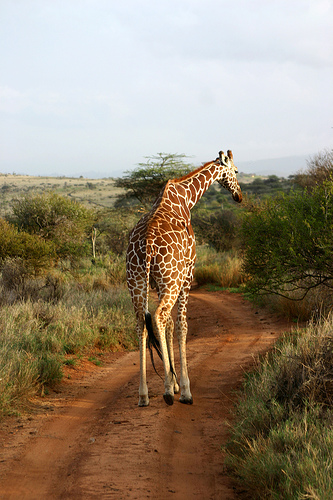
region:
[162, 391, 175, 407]
hoof barely touching the ground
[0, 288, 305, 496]
dirt road used by vehicles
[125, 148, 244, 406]
giraffe walking down a road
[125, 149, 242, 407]
giraffe with its head down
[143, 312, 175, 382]
hair of a giraffe's tail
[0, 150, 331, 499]
giraffe in the wild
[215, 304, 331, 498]
dry grass beside the road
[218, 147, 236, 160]
knobs on a giraffe's head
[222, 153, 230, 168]
right ear of a giraffe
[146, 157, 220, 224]
the mane of a giraffe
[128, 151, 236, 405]
giraffe walking down a dirt road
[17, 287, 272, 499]
a red clay dirt road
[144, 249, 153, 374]
the giraffe's tail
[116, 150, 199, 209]
tallest tree in the distance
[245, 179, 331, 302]
tree on the right next to the giraffe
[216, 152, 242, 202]
the giraffe's head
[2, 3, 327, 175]
clear skies overhead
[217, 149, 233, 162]
the giraffe's horns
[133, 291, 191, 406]
the tall giraffe's four legs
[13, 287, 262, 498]
tire tracks in the dirt road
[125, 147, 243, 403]
a giraffe on a dirt road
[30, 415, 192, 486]
a brown dirt road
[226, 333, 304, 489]
a grassy edge of a road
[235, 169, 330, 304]
a bushy tree by the road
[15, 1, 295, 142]
a blue and white sky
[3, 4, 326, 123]
a blue and white cloudy sky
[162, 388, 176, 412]
a hoof of a animal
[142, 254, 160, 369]
the tail of the aniaml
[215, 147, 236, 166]
the ear of a animal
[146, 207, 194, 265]
tan and cream coat of a animal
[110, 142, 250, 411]
giraffe walking on dirt road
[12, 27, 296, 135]
blue cloudy sky in the distance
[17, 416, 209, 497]
dirt ground where giraffe is walking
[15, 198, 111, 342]
grass and bushes near giraffe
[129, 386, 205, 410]
hooves of a giraffe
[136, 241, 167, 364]
tail of a giraffe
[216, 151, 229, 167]
right ear of a giraffe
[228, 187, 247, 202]
nose and mouth of a giraffe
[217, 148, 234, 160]
horns on a giraffe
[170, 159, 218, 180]
mane of a giraffe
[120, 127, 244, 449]
giraffe is walking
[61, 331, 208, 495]
the road is brown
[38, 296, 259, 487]
the road is made of dirt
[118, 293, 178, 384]
the tip of the tail is black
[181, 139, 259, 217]
the giraffe is looking to the right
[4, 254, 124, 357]
the grass is bushy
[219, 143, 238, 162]
the giraffe has horns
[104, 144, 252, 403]
the giraffe is brown and white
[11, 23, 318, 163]
the sky is overcast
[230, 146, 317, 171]
a mountain in the distance